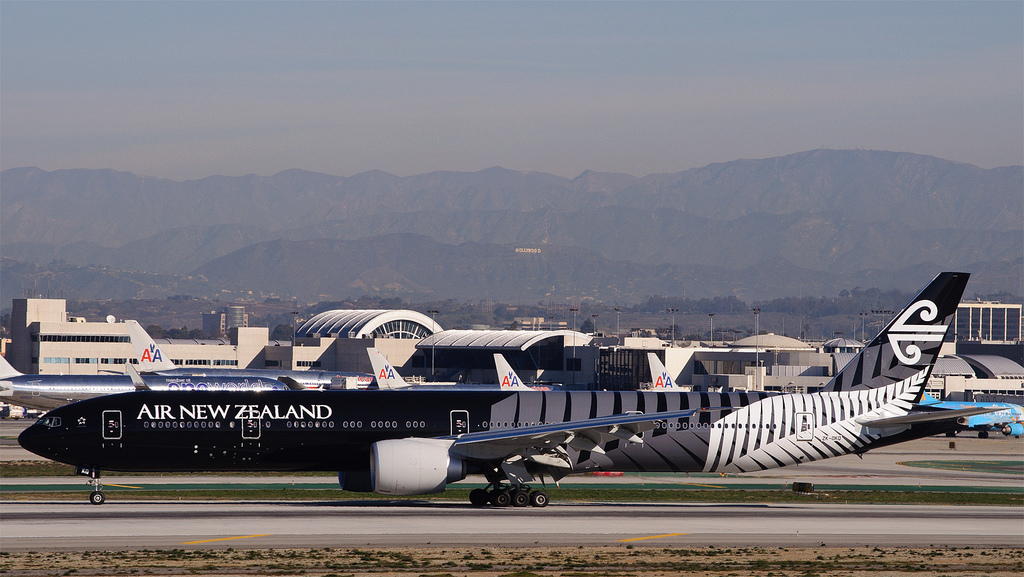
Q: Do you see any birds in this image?
A: No, there are no birds.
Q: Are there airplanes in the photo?
A: Yes, there is an airplane.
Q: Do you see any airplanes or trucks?
A: Yes, there is an airplane.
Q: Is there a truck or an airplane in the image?
A: Yes, there is an airplane.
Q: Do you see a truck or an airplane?
A: Yes, there is an airplane.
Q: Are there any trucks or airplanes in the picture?
A: Yes, there is an airplane.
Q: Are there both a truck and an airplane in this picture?
A: No, there is an airplane but no trucks.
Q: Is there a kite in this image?
A: No, there are no kites.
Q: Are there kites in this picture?
A: No, there are no kites.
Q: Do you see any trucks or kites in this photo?
A: No, there are no kites or trucks.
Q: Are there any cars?
A: No, there are no cars.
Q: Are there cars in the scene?
A: No, there are no cars.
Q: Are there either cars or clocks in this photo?
A: No, there are no cars or clocks.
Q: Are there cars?
A: No, there are no cars.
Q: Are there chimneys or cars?
A: No, there are no cars or chimneys.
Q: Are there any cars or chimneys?
A: No, there are no cars or chimneys.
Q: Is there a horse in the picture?
A: No, there are no horses.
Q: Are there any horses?
A: No, there are no horses.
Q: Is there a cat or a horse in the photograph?
A: No, there are no horses or cats.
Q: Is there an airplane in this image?
A: Yes, there is an airplane.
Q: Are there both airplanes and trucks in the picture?
A: No, there is an airplane but no trucks.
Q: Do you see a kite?
A: No, there are no kites.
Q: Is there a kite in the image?
A: No, there are no kites.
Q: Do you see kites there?
A: No, there are no kites.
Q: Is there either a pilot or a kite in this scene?
A: No, there are no kites or pilots.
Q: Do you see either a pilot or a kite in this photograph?
A: No, there are no kites or pilots.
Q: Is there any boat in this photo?
A: No, there are no boats.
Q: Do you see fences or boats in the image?
A: No, there are no boats or fences.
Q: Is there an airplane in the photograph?
A: Yes, there is an airplane.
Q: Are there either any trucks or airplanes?
A: Yes, there is an airplane.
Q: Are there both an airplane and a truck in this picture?
A: No, there is an airplane but no trucks.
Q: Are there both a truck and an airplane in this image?
A: No, there is an airplane but no trucks.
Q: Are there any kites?
A: No, there are no kites.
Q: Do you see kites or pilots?
A: No, there are no kites or pilots.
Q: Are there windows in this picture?
A: Yes, there are windows.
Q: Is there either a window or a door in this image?
A: Yes, there are windows.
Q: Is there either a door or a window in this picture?
A: Yes, there are windows.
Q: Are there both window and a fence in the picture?
A: No, there are windows but no fences.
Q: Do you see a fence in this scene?
A: No, there are no fences.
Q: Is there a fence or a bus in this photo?
A: No, there are no fences or buses.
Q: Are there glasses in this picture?
A: No, there are no glasses.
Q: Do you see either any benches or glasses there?
A: No, there are no glasses or benches.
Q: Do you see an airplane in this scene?
A: Yes, there is an airplane.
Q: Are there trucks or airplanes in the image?
A: Yes, there is an airplane.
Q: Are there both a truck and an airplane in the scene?
A: No, there is an airplane but no trucks.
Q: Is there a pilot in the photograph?
A: No, there are no pilots.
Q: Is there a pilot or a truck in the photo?
A: No, there are no pilots or trucks.